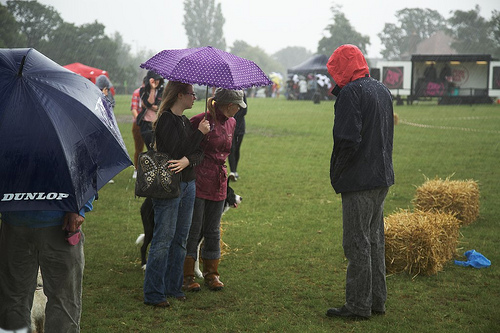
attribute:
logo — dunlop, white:
[3, 190, 69, 204]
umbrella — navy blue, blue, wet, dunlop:
[2, 47, 129, 214]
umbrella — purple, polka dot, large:
[140, 47, 275, 131]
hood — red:
[325, 44, 370, 87]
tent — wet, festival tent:
[288, 53, 338, 101]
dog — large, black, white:
[223, 185, 242, 218]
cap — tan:
[216, 88, 248, 110]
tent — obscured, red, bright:
[61, 62, 108, 86]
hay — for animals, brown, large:
[383, 211, 464, 277]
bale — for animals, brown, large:
[414, 179, 482, 224]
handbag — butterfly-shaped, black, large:
[134, 109, 191, 199]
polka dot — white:
[189, 64, 193, 69]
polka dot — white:
[208, 66, 213, 70]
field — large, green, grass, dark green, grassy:
[80, 93, 499, 331]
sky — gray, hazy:
[0, 2, 499, 58]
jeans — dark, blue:
[145, 181, 193, 303]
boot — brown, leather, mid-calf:
[182, 253, 200, 291]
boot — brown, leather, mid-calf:
[200, 250, 224, 290]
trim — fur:
[198, 250, 225, 259]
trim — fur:
[184, 252, 197, 259]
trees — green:
[377, 4, 498, 60]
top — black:
[158, 110, 207, 181]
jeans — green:
[1, 223, 84, 332]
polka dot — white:
[208, 79, 213, 84]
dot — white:
[89, 70, 95, 75]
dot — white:
[102, 70, 106, 74]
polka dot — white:
[202, 57, 206, 60]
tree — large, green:
[183, 1, 228, 51]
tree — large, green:
[316, 4, 372, 54]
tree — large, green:
[0, 1, 68, 64]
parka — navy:
[328, 78, 395, 194]